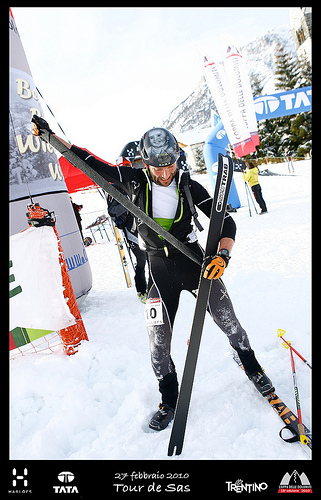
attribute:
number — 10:
[143, 307, 158, 319]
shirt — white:
[150, 183, 178, 218]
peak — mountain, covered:
[230, 21, 285, 63]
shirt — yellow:
[240, 167, 260, 188]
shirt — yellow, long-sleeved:
[244, 166, 259, 186]